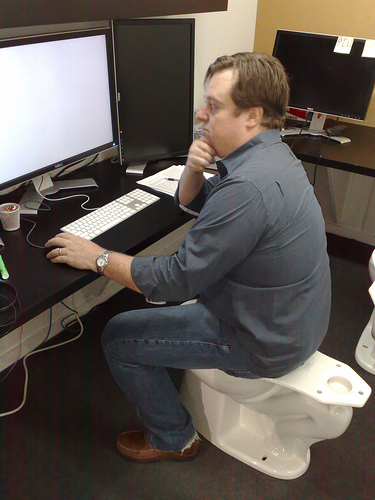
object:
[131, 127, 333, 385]
shirt